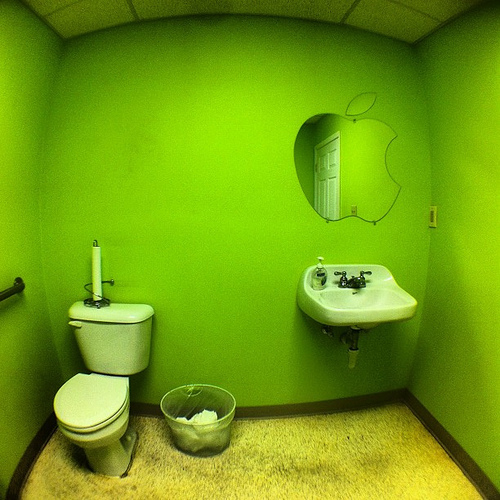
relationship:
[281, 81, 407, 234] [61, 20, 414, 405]
mirror on wall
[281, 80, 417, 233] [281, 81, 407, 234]
apple shaped mirror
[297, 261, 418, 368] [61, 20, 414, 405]
basin on wall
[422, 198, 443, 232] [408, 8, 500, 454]
outlet on wall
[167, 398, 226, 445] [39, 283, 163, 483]
trash beside toilet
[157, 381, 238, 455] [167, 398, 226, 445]
basket of trash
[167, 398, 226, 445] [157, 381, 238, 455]
trash in basket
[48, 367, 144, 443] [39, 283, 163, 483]
seat of toilet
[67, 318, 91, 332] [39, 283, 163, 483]
handle of toilet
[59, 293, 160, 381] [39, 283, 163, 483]
tank of toilet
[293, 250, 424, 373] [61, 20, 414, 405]
basin mounted on wall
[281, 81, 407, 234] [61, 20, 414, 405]
mirror hanging on wall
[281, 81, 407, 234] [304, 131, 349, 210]
mirror has reflection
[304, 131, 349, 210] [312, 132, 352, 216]
reflection of bathroom door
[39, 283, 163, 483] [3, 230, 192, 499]
toilet in corner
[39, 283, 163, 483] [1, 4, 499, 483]
toilet in bathroom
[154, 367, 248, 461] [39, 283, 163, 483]
basket next to toilet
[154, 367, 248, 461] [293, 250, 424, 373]
basket next to basin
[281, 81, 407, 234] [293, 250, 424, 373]
mirror above basin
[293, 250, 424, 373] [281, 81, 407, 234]
basin mounted below mirror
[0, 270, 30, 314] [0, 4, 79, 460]
bar fixed to wall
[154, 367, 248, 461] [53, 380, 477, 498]
basket placed on floor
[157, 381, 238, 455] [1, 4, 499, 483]
basket inside of bathroom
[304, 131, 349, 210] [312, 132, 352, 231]
reflection of bathroom door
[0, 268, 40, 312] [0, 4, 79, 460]
rod hung on wall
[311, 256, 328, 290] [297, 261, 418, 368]
handwash sitting on basin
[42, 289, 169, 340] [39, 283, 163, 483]
lid of toilet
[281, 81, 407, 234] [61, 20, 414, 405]
mirror attached on wall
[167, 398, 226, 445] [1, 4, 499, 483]
trash in bathroom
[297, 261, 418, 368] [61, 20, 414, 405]
basin attached on wall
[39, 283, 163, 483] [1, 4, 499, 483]
toilet inside of bathroom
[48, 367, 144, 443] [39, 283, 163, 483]
seat attached to toilet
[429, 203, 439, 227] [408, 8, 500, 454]
outlet attached on wall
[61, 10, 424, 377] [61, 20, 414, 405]
paint on wall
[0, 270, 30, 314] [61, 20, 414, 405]
bar on wall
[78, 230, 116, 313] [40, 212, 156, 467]
paper towel holder sitting on toilet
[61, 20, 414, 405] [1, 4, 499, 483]
wall insides of bathroom